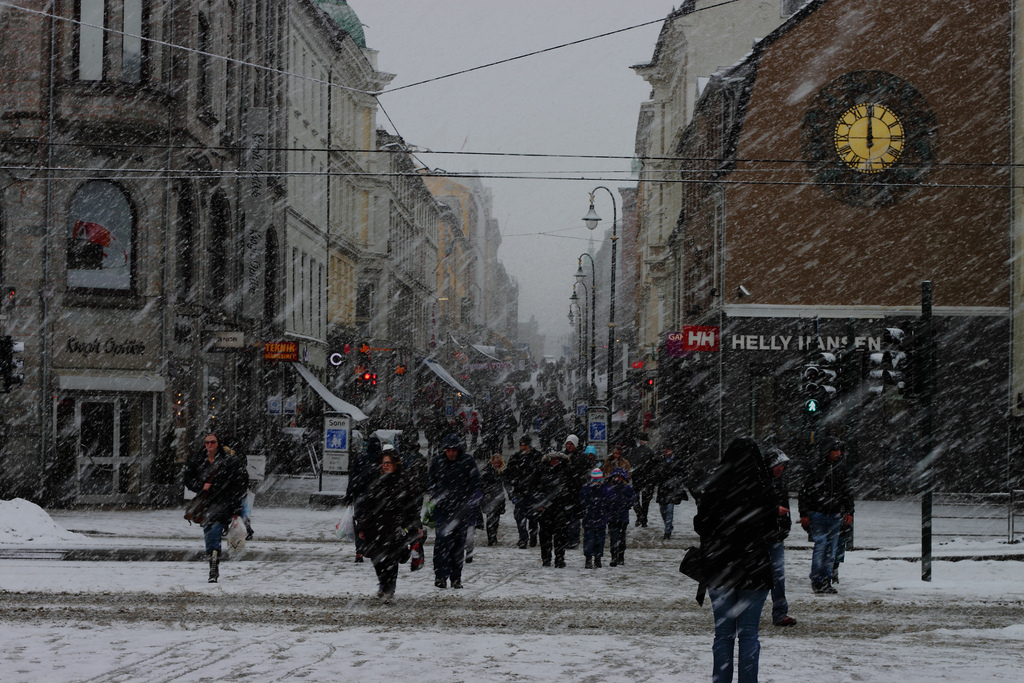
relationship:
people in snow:
[178, 367, 877, 674] [0, 496, 1024, 683]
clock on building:
[810, 69, 939, 212] [7, 10, 1023, 551]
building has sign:
[7, 10, 1023, 551] [720, 310, 886, 380]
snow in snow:
[8, 479, 1021, 667] [0, 496, 1024, 683]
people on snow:
[178, 367, 877, 674] [0, 496, 1024, 683]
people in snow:
[178, 367, 877, 674] [8, 479, 1021, 667]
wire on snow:
[4, 10, 1023, 205] [0, 496, 1024, 683]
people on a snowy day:
[184, 433, 252, 582] [49, 83, 981, 676]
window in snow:
[70, 150, 240, 340] [159, 206, 728, 637]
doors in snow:
[64, 346, 185, 541] [8, 479, 1021, 667]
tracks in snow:
[83, 628, 341, 683] [8, 479, 1021, 667]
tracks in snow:
[194, 478, 720, 677] [8, 479, 1021, 667]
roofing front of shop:
[630, 206, 942, 390] [669, 306, 1005, 524]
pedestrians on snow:
[363, 383, 811, 630] [0, 496, 1024, 683]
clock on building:
[810, 69, 939, 212] [577, 0, 1024, 498]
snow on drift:
[8, 479, 1021, 667] [0, 495, 1010, 608]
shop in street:
[669, 306, 1005, 524] [0, 491, 1010, 677]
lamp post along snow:
[573, 184, 623, 537] [0, 496, 1024, 683]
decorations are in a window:
[56, 207, 145, 285] [52, 154, 161, 308]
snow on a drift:
[8, 479, 1021, 667] [4, 495, 1009, 597]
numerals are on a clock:
[838, 99, 912, 166] [810, 69, 939, 212]